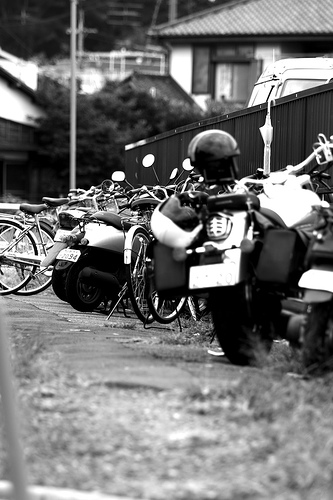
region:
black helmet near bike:
[186, 111, 241, 180]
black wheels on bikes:
[0, 210, 51, 268]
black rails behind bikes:
[127, 89, 319, 175]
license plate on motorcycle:
[49, 246, 74, 264]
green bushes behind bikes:
[45, 98, 233, 193]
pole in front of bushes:
[44, 13, 96, 192]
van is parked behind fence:
[248, 59, 304, 100]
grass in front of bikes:
[82, 388, 288, 472]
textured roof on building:
[176, 1, 331, 48]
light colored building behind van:
[180, 49, 263, 87]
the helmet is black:
[180, 123, 238, 191]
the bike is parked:
[108, 174, 160, 316]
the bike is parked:
[96, 187, 193, 374]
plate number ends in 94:
[47, 240, 83, 270]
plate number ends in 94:
[50, 232, 98, 284]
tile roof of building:
[159, 1, 331, 33]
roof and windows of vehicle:
[250, 56, 331, 105]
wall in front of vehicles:
[124, 58, 332, 187]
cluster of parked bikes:
[0, 127, 330, 370]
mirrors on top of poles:
[109, 151, 190, 185]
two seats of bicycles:
[21, 196, 70, 215]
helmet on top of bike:
[188, 129, 240, 168]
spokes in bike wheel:
[0, 228, 30, 291]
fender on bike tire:
[122, 223, 143, 262]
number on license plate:
[57, 248, 79, 260]